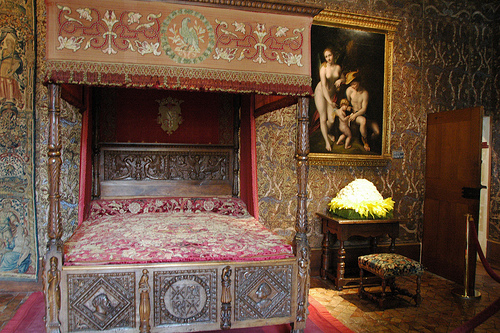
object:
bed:
[56, 141, 302, 333]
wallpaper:
[395, 1, 428, 155]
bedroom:
[2, 2, 499, 332]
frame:
[42, 85, 306, 333]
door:
[421, 106, 487, 290]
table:
[313, 210, 411, 291]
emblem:
[145, 272, 222, 333]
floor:
[307, 306, 444, 331]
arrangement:
[326, 177, 397, 218]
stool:
[354, 251, 425, 311]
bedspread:
[62, 197, 297, 267]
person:
[335, 100, 354, 150]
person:
[344, 72, 371, 151]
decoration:
[152, 93, 186, 136]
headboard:
[92, 94, 239, 201]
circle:
[159, 6, 216, 65]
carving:
[96, 151, 231, 185]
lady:
[313, 45, 343, 152]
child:
[336, 100, 355, 150]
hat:
[342, 67, 362, 85]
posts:
[46, 82, 61, 281]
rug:
[2, 290, 353, 332]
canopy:
[38, 2, 315, 101]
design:
[93, 9, 127, 55]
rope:
[470, 219, 497, 281]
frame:
[297, 7, 402, 173]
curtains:
[78, 86, 259, 218]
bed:
[40, 2, 323, 332]